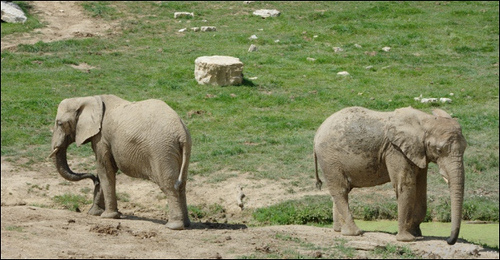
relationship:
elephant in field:
[267, 54, 478, 258] [24, 20, 482, 201]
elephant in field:
[45, 89, 199, 235] [24, 20, 482, 201]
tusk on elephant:
[427, 166, 469, 195] [312, 106, 466, 245]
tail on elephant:
[313, 138, 323, 188] [312, 106, 466, 245]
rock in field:
[420, 95, 448, 105] [6, 4, 483, 182]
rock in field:
[0, 1, 27, 26] [6, 4, 483, 182]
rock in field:
[172, 11, 194, 18] [6, 4, 483, 182]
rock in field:
[252, 8, 279, 18] [6, 4, 483, 182]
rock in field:
[173, 25, 214, 33] [6, 4, 483, 182]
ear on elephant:
[73, 96, 104, 148] [312, 106, 466, 245]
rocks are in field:
[170, 3, 457, 104] [0, 2, 497, 247]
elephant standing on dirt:
[45, 89, 199, 235] [29, 202, 136, 252]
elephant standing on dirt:
[312, 106, 466, 245] [29, 202, 136, 252]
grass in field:
[112, 52, 189, 97] [6, 9, 491, 149]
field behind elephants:
[6, 9, 491, 149] [15, 54, 499, 233]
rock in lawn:
[336, 69, 352, 78] [260, 6, 487, 97]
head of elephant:
[44, 89, 99, 193] [45, 89, 199, 235]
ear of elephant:
[75, 95, 104, 147] [45, 89, 199, 235]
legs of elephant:
[75, 161, 187, 246] [34, 69, 275, 203]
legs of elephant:
[155, 154, 207, 234] [45, 89, 199, 235]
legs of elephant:
[320, 168, 367, 240] [297, 91, 475, 245]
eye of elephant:
[48, 111, 66, 133] [45, 89, 199, 235]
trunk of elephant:
[445, 158, 465, 245] [312, 106, 466, 245]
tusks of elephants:
[42, 143, 66, 160] [36, 92, 194, 230]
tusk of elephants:
[441, 175, 448, 183] [311, 107, 463, 244]